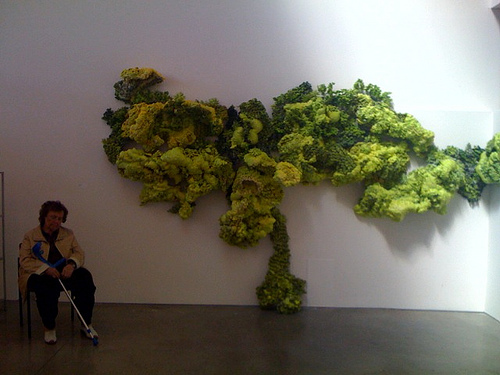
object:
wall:
[0, 0, 500, 320]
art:
[101, 67, 499, 313]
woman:
[18, 199, 100, 346]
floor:
[0, 302, 499, 375]